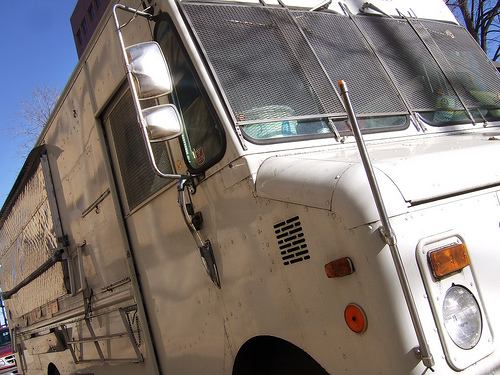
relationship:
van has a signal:
[0, 0, 499, 373] [322, 257, 353, 279]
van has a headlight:
[0, 0, 499, 373] [440, 284, 482, 351]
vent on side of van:
[271, 215, 311, 266] [0, 0, 499, 373]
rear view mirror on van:
[122, 41, 175, 101] [0, 0, 499, 373]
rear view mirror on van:
[137, 103, 184, 144] [0, 0, 499, 373]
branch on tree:
[479, 2, 500, 55] [447, 0, 500, 62]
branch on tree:
[469, 0, 476, 21] [447, 0, 500, 62]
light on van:
[427, 242, 472, 282] [0, 0, 499, 373]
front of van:
[258, 125, 499, 374] [0, 0, 499, 373]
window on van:
[153, 17, 223, 172] [0, 0, 499, 373]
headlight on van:
[440, 284, 482, 351] [0, 0, 499, 373]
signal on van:
[322, 257, 353, 279] [0, 0, 499, 373]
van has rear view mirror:
[0, 0, 499, 373] [122, 41, 175, 101]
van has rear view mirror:
[0, 0, 499, 373] [137, 103, 184, 144]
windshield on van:
[188, 1, 409, 142] [0, 0, 499, 373]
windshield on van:
[359, 17, 499, 126] [0, 0, 499, 373]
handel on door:
[174, 175, 222, 289] [99, 90, 226, 374]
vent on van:
[271, 215, 311, 266] [0, 0, 499, 373]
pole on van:
[337, 79, 434, 371] [0, 0, 499, 373]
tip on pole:
[337, 78, 345, 85] [337, 79, 434, 371]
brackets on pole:
[380, 226, 397, 247] [337, 79, 434, 371]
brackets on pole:
[415, 346, 430, 357] [337, 79, 434, 371]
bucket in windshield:
[239, 105, 299, 139] [188, 1, 409, 142]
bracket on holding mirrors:
[182, 169, 196, 195] [112, 4, 196, 178]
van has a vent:
[0, 0, 499, 373] [271, 215, 311, 266]